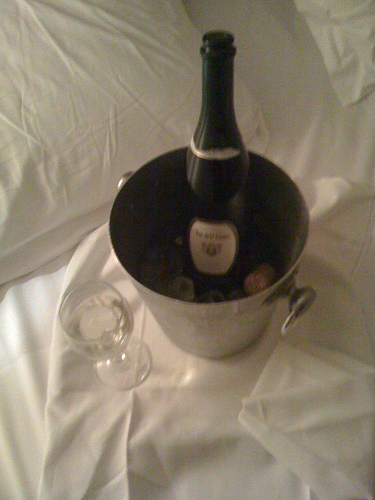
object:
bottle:
[184, 31, 249, 296]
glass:
[55, 277, 150, 389]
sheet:
[295, 0, 374, 110]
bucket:
[110, 145, 310, 359]